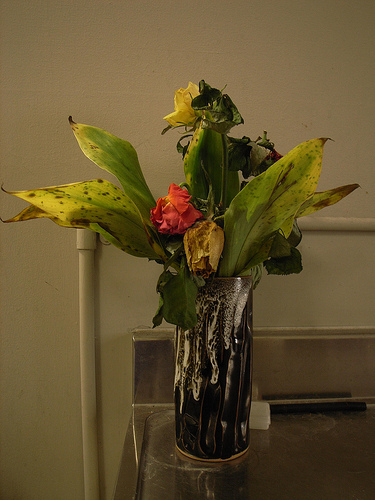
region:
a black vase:
[179, 276, 248, 459]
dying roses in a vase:
[157, 195, 223, 274]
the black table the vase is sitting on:
[143, 418, 371, 485]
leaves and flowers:
[22, 88, 320, 287]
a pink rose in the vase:
[154, 181, 199, 223]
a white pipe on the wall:
[75, 227, 106, 450]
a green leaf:
[70, 117, 156, 215]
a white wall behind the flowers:
[10, 10, 344, 58]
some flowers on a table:
[60, 109, 340, 458]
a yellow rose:
[166, 81, 203, 123]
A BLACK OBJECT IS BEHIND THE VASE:
[272, 395, 366, 417]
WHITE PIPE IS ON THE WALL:
[74, 232, 102, 496]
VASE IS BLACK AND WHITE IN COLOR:
[169, 272, 256, 464]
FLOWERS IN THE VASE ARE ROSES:
[142, 84, 291, 276]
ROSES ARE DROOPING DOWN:
[147, 182, 234, 268]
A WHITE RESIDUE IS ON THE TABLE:
[139, 413, 186, 479]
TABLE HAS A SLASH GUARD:
[129, 327, 373, 398]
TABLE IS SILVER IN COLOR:
[113, 326, 372, 499]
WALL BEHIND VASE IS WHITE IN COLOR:
[10, 13, 374, 118]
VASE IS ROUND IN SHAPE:
[171, 272, 252, 464]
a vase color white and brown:
[166, 272, 264, 468]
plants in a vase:
[0, 60, 367, 472]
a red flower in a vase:
[148, 173, 241, 296]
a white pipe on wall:
[63, 224, 112, 498]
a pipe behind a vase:
[282, 208, 373, 240]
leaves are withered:
[2, 176, 122, 246]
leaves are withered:
[267, 130, 329, 206]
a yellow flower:
[157, 70, 202, 137]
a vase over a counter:
[114, 268, 371, 495]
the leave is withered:
[178, 222, 226, 285]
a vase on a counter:
[163, 256, 259, 469]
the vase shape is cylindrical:
[162, 270, 260, 465]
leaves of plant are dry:
[1, 180, 119, 234]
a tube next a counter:
[68, 226, 161, 494]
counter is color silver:
[113, 325, 373, 496]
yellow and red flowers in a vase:
[144, 67, 262, 465]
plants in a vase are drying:
[8, 70, 364, 468]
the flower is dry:
[174, 219, 223, 289]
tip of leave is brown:
[308, 177, 364, 218]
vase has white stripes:
[163, 270, 265, 466]